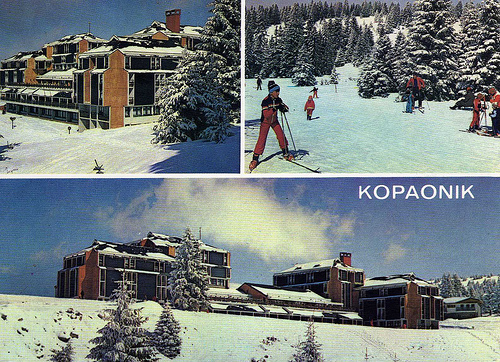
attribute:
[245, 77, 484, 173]
ground — snow covered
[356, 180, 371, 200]
letter — white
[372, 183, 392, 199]
letter — white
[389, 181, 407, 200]
letter — white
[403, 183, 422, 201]
letter — white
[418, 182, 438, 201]
letter — white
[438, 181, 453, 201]
letter — white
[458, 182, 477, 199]
letter — white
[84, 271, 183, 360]
trees — snow covered, pine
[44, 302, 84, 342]
rocks — snow covered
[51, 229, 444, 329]
lodge — ski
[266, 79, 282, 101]
head — boy's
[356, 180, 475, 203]
name — Russian city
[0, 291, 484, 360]
hill — snow covered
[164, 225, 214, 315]
tree — large, pine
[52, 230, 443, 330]
building — large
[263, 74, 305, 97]
hat — blue, black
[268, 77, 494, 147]
people — skiing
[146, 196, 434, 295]
sky — white, puffy, cloudy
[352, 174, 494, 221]
word — written, white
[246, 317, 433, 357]
snow — white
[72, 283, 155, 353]
tree — green, large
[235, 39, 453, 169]
people — skiing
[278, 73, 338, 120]
child — dressed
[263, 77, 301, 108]
hat — black, white, blue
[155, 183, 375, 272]
cloud — large, white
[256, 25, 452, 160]
hill — snowy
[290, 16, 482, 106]
trees — snow covered, pine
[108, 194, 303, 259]
cloud — big, white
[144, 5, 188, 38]
chimney — red, brick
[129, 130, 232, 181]
shadow — cast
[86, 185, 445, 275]
sky — blue, above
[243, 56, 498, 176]
people — wearing red, lots